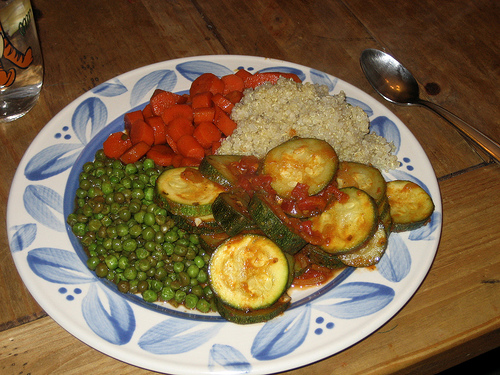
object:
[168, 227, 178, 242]
pea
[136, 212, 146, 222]
pea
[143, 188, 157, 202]
pea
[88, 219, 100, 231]
pea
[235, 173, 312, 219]
sauce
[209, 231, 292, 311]
zucchini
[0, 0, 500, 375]
table